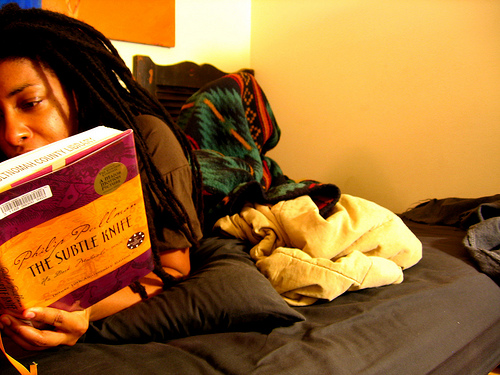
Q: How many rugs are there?
A: One.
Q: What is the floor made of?
A: Wood.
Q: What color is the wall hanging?
A: Blue and orange.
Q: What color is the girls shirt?
A: Brown.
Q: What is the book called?
A: The Subtle Knife.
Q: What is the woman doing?
A: Reading.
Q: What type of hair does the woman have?
A: Dreadlocks.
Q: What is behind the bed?
A: Chair.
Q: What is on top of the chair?
A: Jacket.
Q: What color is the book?
A: Red and yellow.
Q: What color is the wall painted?
A: Yellow.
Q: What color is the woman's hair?
A: Black.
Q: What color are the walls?
A: Yellow.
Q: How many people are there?
A: One.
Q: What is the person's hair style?
A: Dreadlocks.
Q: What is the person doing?
A: Reading.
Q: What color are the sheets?
A: Brown.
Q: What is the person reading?
A: A book.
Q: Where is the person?
A: Lying on a bed.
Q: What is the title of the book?
A: The Subtle Knife.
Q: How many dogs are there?
A: None.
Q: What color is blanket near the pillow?
A: White.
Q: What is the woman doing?
A: Reading.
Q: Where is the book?
A: Woman's hand.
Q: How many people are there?
A: One.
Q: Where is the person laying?
A: The bed.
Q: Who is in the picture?
A: A black woman.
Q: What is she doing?
A: Reading a book.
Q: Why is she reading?
A: She likes the book.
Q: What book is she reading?
A: The subtle knife.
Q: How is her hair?
A: In dreadlocks.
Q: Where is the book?
A: In her hands.